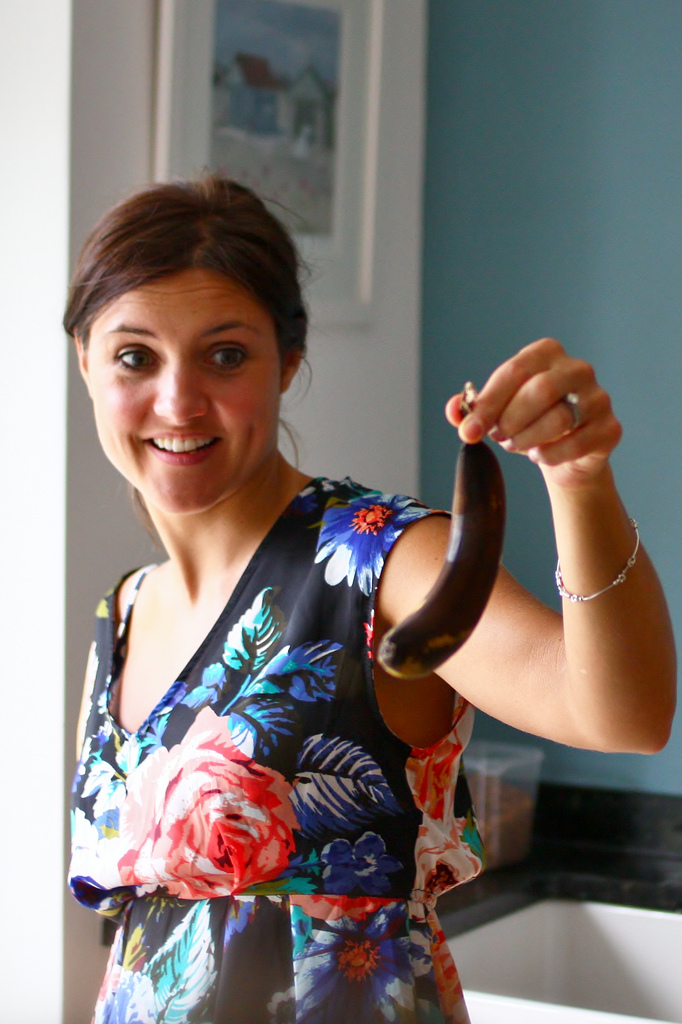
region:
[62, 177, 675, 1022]
Happy woman in a floral dress.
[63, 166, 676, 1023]
Joyous lady holding an old banana.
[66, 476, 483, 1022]
Floral patterned dress on the woman.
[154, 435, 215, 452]
Pearly white teeth of woman.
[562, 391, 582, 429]
Diamond ring the woman is wearing.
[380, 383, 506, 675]
Old blackened banana in lady's hand.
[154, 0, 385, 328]
Painting on wall behind woman.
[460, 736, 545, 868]
Plastic contained of dog food behind woman.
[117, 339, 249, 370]
Dark brown eyes of happy woman.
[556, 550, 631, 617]
she is wearing a bracelet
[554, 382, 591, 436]
she is wearing a ring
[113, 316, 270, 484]
she looks very surprised at the banana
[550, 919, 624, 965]
the sink is white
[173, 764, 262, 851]
the flower is pink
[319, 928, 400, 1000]
the flower is blue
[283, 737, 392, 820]
blue on black dress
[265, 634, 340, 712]
blue on black dress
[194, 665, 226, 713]
blue on black dress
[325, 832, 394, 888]
blue on black dress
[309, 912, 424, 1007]
blue on black dress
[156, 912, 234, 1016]
blue on black dress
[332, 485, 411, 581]
blue on black dress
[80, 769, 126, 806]
blue on black dress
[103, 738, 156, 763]
blue on black dress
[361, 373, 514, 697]
A brown banana in the woman's hand.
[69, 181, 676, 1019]
A woman holding a banana.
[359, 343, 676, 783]
The woman holds an over ripe banana.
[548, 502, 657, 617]
A bracelet on the woman's wrist.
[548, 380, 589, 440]
A diamond ring on the woman's finger.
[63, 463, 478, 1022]
The woman wears a black dress with a floral print.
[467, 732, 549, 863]
A plastic container on the counter.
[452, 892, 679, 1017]
A white sink behind the woman.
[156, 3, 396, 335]
A picture with a white frame hangs from the wall.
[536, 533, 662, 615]
The silver bracelet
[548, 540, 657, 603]
A silver bracelet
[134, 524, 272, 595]
The neck of the person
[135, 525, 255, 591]
A neck of the person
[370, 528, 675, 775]
A right arm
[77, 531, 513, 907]
The top portion of the dress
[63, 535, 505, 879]
A top portion of the dress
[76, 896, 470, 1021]
The bottom portion of the dress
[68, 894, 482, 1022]
A bottom portion of the dress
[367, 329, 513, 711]
fingers holding a banana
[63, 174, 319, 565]
the lady is showing teeth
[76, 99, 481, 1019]
lady wearing a floral top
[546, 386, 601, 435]
a ring on a finger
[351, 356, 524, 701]
the banana is brown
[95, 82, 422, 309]
a picture behind lady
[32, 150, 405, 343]
the hair is brown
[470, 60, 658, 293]
the paint is blue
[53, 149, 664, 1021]
woman holding overripe banana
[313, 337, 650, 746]
a woman holding a banana